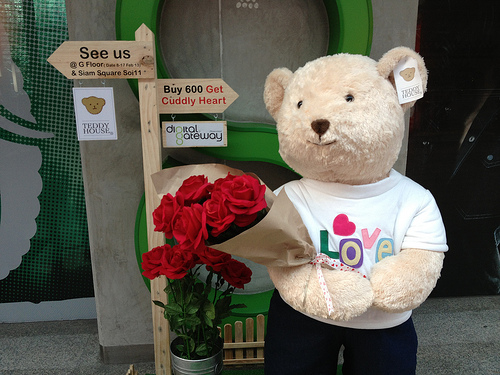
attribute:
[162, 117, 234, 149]
sign —  white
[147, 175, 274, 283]
flowers —  red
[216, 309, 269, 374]
fence —   wood,  picket,  small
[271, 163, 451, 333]
shirt — white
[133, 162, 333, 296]
flower — red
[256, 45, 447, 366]
bear —  stuffed, tan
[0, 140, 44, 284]
paint —  White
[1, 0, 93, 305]
window —  glass 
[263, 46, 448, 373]
stuffed bear —  stuffed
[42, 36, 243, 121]
arrows —  direction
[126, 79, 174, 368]
post —  wooden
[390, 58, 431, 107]
tag — white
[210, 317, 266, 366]
fence —  picket,  mini 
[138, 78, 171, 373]
pole — wooden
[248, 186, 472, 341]
shirt —  white,  short sleeve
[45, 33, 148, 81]
sign — brown, black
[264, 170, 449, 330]
shirt — tee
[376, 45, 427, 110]
ear —  bear's